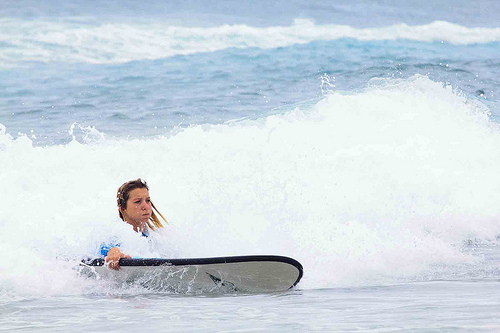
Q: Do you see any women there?
A: Yes, there is a woman.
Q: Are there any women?
A: Yes, there is a woman.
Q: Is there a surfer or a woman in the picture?
A: Yes, there is a woman.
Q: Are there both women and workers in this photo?
A: No, there is a woman but no workers.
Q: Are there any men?
A: No, there are no men.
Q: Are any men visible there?
A: No, there are no men.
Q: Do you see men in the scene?
A: No, there are no men.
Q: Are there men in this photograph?
A: No, there are no men.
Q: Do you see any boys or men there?
A: No, there are no men or boys.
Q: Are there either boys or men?
A: No, there are no men or boys.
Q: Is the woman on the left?
A: Yes, the woman is on the left of the image.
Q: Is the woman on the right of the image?
A: No, the woman is on the left of the image.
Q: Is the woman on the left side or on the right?
A: The woman is on the left of the image.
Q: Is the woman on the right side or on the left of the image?
A: The woman is on the left of the image.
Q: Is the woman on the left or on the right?
A: The woman is on the left of the image.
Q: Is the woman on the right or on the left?
A: The woman is on the left of the image.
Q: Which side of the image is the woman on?
A: The woman is on the left of the image.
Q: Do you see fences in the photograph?
A: No, there are no fences.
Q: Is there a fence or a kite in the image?
A: No, there are no fences or kites.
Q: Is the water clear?
A: Yes, the water is clear.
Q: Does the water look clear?
A: Yes, the water is clear.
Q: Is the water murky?
A: No, the water is clear.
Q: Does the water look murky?
A: No, the water is clear.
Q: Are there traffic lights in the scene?
A: No, there are no traffic lights.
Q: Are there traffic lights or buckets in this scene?
A: No, there are no traffic lights or buckets.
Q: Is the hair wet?
A: Yes, the hair is wet.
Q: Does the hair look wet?
A: Yes, the hair is wet.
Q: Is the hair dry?
A: No, the hair is wet.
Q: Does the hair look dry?
A: No, the hair is wet.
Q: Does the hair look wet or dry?
A: The hair is wet.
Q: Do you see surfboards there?
A: Yes, there is a surfboard.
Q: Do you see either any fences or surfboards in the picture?
A: Yes, there is a surfboard.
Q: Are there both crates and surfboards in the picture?
A: No, there is a surfboard but no crates.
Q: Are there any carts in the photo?
A: No, there are no carts.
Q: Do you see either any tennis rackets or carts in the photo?
A: No, there are no carts or tennis rackets.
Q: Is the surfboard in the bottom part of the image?
A: Yes, the surfboard is in the bottom of the image.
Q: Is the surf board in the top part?
A: No, the surf board is in the bottom of the image.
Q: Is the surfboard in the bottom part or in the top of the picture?
A: The surfboard is in the bottom of the image.